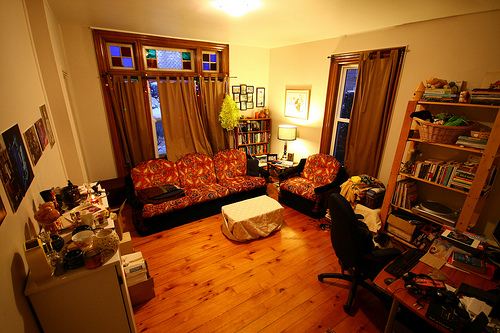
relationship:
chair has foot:
[318, 193, 403, 313] [314, 269, 352, 283]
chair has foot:
[318, 193, 403, 313] [340, 278, 360, 315]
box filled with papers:
[129, 260, 155, 304] [120, 250, 147, 287]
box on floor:
[126, 255, 151, 304] [117, 175, 415, 331]